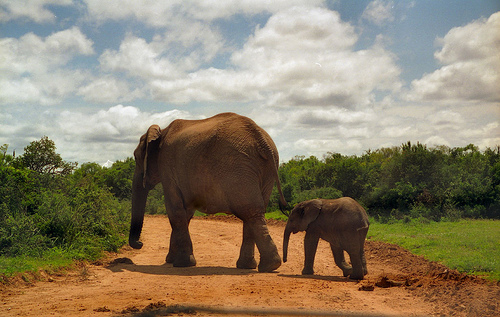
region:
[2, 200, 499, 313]
Red dirt road curves to left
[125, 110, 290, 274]
Adult mother elephant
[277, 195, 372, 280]
Baby elephant walking on a road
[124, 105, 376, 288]
Mother and baby elephants walking on a road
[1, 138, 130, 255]
Shrubbery beside the dirt road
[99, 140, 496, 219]
Bushes in the background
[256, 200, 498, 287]
Short green grass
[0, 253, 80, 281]
Short green grass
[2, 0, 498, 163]
Puffy white and grey clouds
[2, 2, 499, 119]
Patches of blue sky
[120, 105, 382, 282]
two elephants crossing over a dirt road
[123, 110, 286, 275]
a mother elephant leading her baby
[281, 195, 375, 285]
a baby elephant following its mother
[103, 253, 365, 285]
shadows of the two elephants cast on the dirt road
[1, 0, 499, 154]
a lot of clouds in the sky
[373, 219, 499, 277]
a small field of grass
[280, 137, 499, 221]
a line of trees and bushes behind the grassy field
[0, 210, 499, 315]
a crude dirt road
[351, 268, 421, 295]
chunks of dirt on the road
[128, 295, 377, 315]
a shadow cast on the dirt road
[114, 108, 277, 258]
large gray elephant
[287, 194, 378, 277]
baby elephant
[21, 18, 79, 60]
white clouds on blue sky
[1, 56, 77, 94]
white clouds on blue sky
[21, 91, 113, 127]
white clouds on blue sky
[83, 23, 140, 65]
white clouds on blue sky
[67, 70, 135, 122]
white clouds on blue sky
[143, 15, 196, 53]
white clouds on blue sky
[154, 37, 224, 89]
white clouds on blue sky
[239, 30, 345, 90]
white clouds on blue sky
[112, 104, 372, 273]
two elephants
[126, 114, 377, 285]
the elephants are standing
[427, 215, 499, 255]
a field of green grass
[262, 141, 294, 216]
the elephants tail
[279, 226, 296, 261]
the elephants trunk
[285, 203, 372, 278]
a small elephant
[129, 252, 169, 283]
a shadow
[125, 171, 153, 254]
the elephants trunk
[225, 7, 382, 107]
white clouds in the sky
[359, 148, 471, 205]
the bushes are green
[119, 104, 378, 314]
Two elephants walking along the trail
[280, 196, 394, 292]
Baby elephant with four legs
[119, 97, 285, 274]
Mother elephant with four legs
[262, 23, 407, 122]
Sunny day with white clouds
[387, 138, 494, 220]
Green trees in background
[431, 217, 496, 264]
Green grass located in background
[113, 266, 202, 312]
Brown clay pathway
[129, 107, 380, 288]
Two brown elephants with four legs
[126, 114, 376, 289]
Small elephant following bigger elephant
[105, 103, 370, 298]
Bigger elephant leading the trail